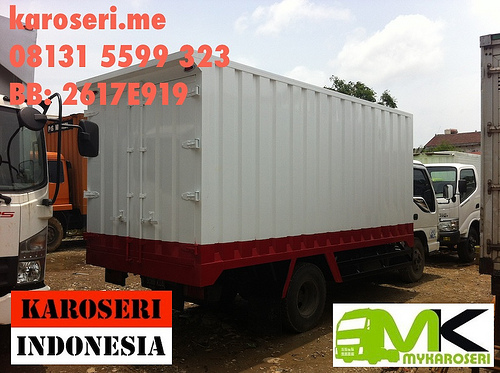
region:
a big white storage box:
[108, 85, 422, 260]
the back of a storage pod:
[71, 96, 221, 237]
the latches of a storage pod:
[111, 139, 156, 200]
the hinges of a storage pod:
[77, 181, 109, 212]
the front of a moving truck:
[401, 149, 445, 261]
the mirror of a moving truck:
[435, 178, 463, 202]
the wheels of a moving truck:
[204, 262, 332, 322]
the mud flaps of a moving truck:
[94, 259, 155, 293]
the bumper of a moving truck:
[84, 241, 208, 291]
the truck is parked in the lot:
[84, 58, 438, 315]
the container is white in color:
[81, 53, 416, 279]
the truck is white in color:
[421, 148, 483, 255]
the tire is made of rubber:
[396, 234, 431, 282]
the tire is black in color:
[396, 232, 425, 284]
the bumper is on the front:
[438, 216, 459, 236]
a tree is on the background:
[325, 76, 398, 112]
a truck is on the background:
[38, 112, 100, 242]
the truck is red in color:
[41, 114, 98, 238]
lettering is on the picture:
[8, 4, 232, 124]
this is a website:
[2, 2, 188, 41]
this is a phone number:
[2, 35, 244, 75]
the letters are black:
[4, 281, 184, 371]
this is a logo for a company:
[323, 298, 498, 371]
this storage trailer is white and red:
[66, 53, 424, 287]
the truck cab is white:
[405, 148, 466, 283]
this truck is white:
[433, 135, 498, 284]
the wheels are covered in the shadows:
[180, 243, 440, 333]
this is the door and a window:
[410, 155, 440, 255]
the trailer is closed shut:
[72, 58, 214, 282]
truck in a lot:
[51, 51, 443, 315]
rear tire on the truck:
[260, 268, 342, 330]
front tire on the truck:
[398, 244, 444, 281]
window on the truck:
[399, 184, 436, 206]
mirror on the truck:
[66, 113, 106, 162]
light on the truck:
[7, 256, 48, 277]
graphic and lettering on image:
[324, 275, 485, 371]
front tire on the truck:
[458, 227, 478, 258]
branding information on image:
[3, 293, 168, 361]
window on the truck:
[433, 170, 453, 195]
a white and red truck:
[73, 42, 440, 334]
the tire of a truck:
[265, 258, 333, 335]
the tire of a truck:
[398, 232, 436, 287]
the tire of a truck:
[458, 219, 480, 266]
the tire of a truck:
[35, 212, 67, 252]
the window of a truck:
[410, 164, 439, 214]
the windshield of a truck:
[418, 163, 458, 200]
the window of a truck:
[455, 167, 480, 207]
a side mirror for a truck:
[77, 117, 101, 160]